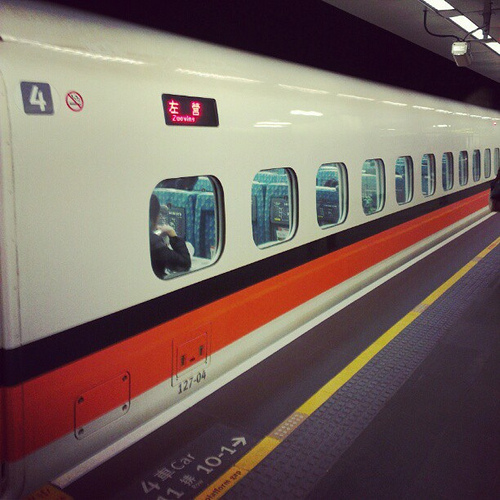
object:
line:
[193, 237, 500, 500]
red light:
[162, 94, 219, 127]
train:
[0, 0, 500, 498]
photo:
[0, 2, 497, 500]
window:
[472, 149, 481, 182]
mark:
[346, 354, 372, 369]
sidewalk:
[28, 214, 500, 500]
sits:
[264, 182, 289, 241]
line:
[4, 180, 494, 460]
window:
[443, 152, 454, 190]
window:
[422, 154, 436, 196]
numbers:
[197, 446, 237, 474]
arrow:
[231, 436, 247, 447]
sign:
[66, 91, 85, 112]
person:
[150, 194, 191, 279]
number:
[178, 370, 206, 394]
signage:
[163, 94, 218, 129]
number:
[28, 85, 48, 113]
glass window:
[150, 176, 226, 281]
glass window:
[251, 167, 297, 250]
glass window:
[315, 162, 349, 229]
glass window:
[361, 159, 384, 216]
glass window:
[395, 156, 414, 207]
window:
[459, 151, 469, 187]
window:
[484, 148, 492, 179]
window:
[494, 148, 500, 174]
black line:
[376, 281, 500, 422]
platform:
[37, 212, 499, 499]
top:
[149, 230, 192, 278]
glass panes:
[149, 175, 222, 280]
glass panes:
[250, 166, 298, 248]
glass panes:
[312, 164, 348, 230]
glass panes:
[360, 158, 386, 215]